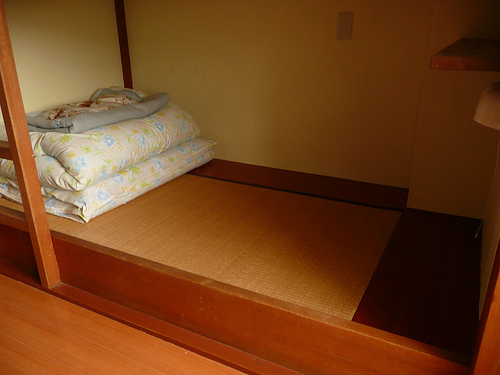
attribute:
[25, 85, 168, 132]
pillow case — blue, yellow, green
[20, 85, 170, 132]
blanket — blue, brown, designed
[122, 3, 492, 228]
wall — trim, yellow, brown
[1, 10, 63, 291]
ladder — brown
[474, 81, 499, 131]
lamp — white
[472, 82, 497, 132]
light — brown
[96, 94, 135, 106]
flower — blue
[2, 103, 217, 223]
comforter — whtie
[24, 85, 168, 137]
sheet — blue, yellow, wrinkled, white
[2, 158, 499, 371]
bed — bunk, wooden, tan, molding, brown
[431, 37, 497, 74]
shelf — hung, brown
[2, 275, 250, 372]
floor — wooden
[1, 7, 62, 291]
pillar — brown